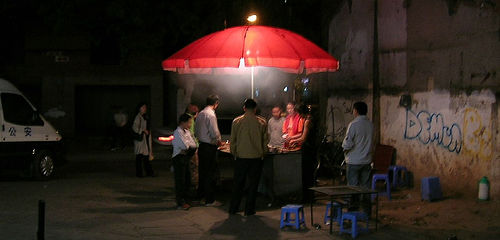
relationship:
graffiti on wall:
[402, 106, 463, 154] [323, 0, 500, 200]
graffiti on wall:
[461, 109, 494, 161] [323, 0, 500, 200]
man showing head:
[228, 97, 270, 215] [243, 98, 259, 111]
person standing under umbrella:
[196, 92, 223, 207] [163, 25, 342, 101]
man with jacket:
[342, 102, 378, 219] [342, 114, 375, 165]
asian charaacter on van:
[7, 126, 34, 138] [2, 74, 69, 183]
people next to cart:
[173, 91, 318, 216] [217, 139, 305, 207]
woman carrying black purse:
[132, 101, 158, 180] [130, 127, 145, 143]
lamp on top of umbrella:
[246, 14, 257, 26] [163, 25, 342, 101]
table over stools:
[307, 184, 381, 234] [323, 200, 372, 239]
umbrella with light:
[163, 25, 342, 101] [227, 26, 274, 45]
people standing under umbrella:
[173, 91, 318, 216] [163, 25, 342, 101]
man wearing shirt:
[173, 113, 198, 210] [172, 127, 198, 158]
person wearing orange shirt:
[281, 101, 303, 151] [282, 114, 304, 147]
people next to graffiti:
[173, 91, 318, 216] [402, 106, 463, 154]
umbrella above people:
[163, 25, 342, 101] [173, 91, 318, 216]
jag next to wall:
[477, 175, 491, 203] [323, 0, 500, 200]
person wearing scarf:
[281, 101, 303, 151] [285, 115, 301, 137]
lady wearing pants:
[112, 109, 129, 153] [113, 124, 127, 152]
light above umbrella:
[246, 14, 257, 26] [163, 25, 342, 101]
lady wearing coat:
[132, 101, 158, 180] [132, 112, 155, 156]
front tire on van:
[33, 148, 58, 182] [2, 74, 69, 183]